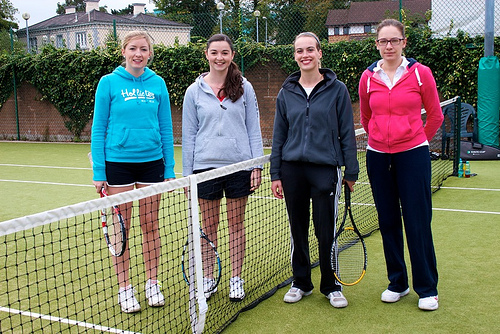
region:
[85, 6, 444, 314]
four girls on the tennis court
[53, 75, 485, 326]
a net across the court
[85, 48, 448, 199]
the women are wearing sweaters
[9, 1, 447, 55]
a few homes are in the background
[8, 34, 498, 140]
some vines grow up against the wall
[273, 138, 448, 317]
the two women are wearing pants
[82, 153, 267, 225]
these two women are wearing shorts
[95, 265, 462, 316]
all four girls are wearing white tennis shoes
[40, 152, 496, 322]
the court is green in color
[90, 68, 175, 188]
the girls sweater is blue in color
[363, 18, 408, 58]
girl wearing brown glasses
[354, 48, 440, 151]
red long sleeved fleece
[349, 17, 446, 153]
girl wearing fleece jacket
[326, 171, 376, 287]
black and yellow tennis racket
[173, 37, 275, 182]
girl wearing grey fleece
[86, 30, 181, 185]
girl wearing light blue fleece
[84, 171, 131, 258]
red white and blue tennis racket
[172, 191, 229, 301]
blue and white tennis racket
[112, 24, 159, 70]
girl with blonde hair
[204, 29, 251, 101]
girl with long brown hair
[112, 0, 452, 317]
women are standing posing for the picture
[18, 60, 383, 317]
3 women are holding tennis rackets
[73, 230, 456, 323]
all the women are wearing sneakers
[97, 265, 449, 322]
all the sneakers are white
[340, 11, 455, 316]
the woman on the end is wearing glasses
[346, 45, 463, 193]
the sweatshirt is pink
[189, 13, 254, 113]
the girl is wearing a ponytail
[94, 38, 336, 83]
3 women are smiling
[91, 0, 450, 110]
all the women are wearing ponytails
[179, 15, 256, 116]
the woman has dark brown hair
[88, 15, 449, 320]
four women on a tennis court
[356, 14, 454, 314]
woman with hands behind her back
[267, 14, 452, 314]
women on the right side of the net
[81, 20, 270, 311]
women on the left side of the net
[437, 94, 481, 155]
blue plastic chair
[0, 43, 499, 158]
brick fence near a tennis court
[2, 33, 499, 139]
green plants growing on brick wall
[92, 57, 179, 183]
blue hoodie from hollister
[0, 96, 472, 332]
net crossing the court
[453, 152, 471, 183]
drinks on the ground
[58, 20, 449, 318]
Four woman standing on tennis court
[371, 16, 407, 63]
Woman sporting bun and glasses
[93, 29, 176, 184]
Woman in blue pull over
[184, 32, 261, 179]
Woman in grey jacket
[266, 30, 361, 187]
Woman in black jacket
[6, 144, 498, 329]
Green grass tennis court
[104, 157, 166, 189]
Athletic shorts with white trim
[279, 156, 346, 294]
Black sweats with white stripes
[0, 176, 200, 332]
Panel of white and black tennis court net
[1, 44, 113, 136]
Ivy hanging over brick wall